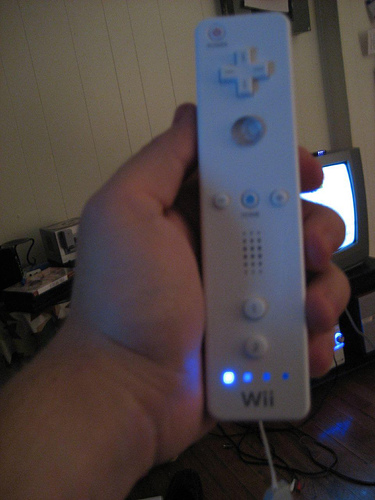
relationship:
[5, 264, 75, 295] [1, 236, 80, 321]
book on shelf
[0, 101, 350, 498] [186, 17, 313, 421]
someone holding controller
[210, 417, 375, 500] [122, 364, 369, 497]
cords on floor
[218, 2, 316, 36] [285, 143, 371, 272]
picture above television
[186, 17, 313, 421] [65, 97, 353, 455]
controller in hand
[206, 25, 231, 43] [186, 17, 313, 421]
button on controller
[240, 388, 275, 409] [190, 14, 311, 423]
graphic on controller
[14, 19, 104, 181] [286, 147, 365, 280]
wall behind television